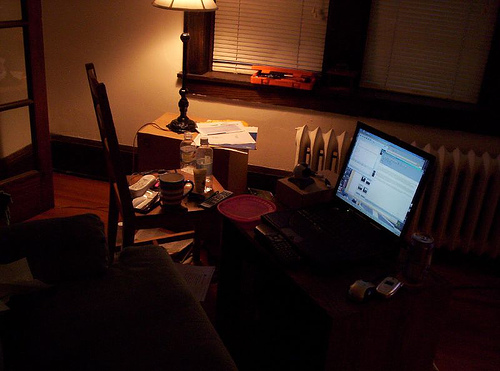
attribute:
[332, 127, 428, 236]
screen — on, flat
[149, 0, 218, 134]
lamp — on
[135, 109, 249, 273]
table — tan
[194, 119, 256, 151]
papers — white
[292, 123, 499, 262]
radiator — white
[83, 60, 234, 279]
chair — wooden, cluttered, straight back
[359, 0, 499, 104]
blinds — closed, white, mini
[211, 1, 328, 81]
blinds — closed, white, mini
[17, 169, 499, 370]
floor — brown, wooden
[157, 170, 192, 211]
coffee mug — striped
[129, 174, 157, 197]
cordless phone — white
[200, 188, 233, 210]
remote — black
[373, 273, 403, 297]
cellphone — flip, silver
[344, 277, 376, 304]
mouse — silver, black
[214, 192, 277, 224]
plate — red, plastic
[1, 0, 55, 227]
door — large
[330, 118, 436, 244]
monitor — black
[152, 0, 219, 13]
shade — white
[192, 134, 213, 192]
bottle — clear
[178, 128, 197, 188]
bottle — clear